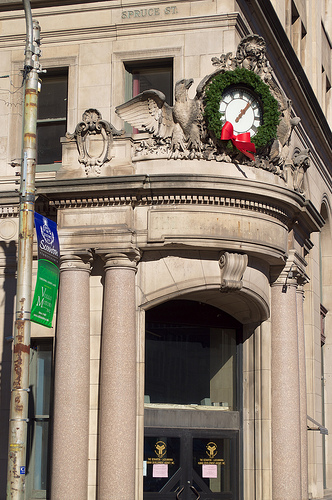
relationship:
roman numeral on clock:
[236, 88, 247, 100] [216, 83, 263, 138]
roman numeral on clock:
[251, 112, 263, 121] [216, 83, 263, 138]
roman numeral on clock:
[227, 90, 236, 99] [216, 83, 263, 138]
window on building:
[192, 436, 235, 493] [0, 0, 330, 498]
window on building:
[91, 28, 192, 152] [56, 11, 309, 280]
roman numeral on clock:
[236, 90, 247, 99] [215, 85, 269, 140]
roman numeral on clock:
[238, 89, 242, 98] [220, 89, 259, 137]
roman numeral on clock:
[229, 90, 234, 99] [220, 89, 259, 137]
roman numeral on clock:
[221, 99, 230, 105] [220, 89, 259, 137]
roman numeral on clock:
[252, 124, 258, 132] [220, 89, 259, 137]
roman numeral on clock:
[217, 111, 225, 115] [220, 89, 259, 137]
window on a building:
[115, 44, 182, 144] [20, 15, 314, 477]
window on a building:
[22, 65, 68, 163] [0, 0, 330, 498]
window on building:
[22, 65, 68, 163] [0, 0, 330, 498]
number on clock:
[236, 92, 245, 101] [194, 74, 274, 131]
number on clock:
[251, 124, 259, 132] [214, 87, 261, 136]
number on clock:
[252, 112, 265, 121] [214, 87, 261, 136]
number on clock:
[228, 93, 235, 100] [214, 87, 261, 136]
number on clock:
[219, 94, 230, 107] [214, 87, 261, 136]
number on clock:
[237, 89, 243, 99] [214, 87, 261, 136]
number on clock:
[252, 112, 265, 121] [214, 81, 267, 145]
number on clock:
[216, 108, 226, 116] [214, 81, 267, 145]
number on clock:
[219, 94, 230, 107] [214, 81, 267, 145]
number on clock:
[228, 93, 235, 100] [214, 81, 267, 145]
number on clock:
[237, 89, 243, 99] [214, 81, 267, 145]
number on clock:
[250, 103, 259, 112] [212, 80, 266, 135]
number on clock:
[250, 103, 259, 112] [196, 58, 280, 158]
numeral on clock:
[251, 121, 260, 129] [199, 64, 276, 157]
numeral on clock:
[219, 113, 226, 120] [213, 91, 272, 140]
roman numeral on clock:
[245, 96, 253, 106] [196, 57, 277, 167]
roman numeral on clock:
[226, 85, 236, 101] [216, 91, 261, 144]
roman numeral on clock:
[236, 89, 245, 99] [216, 83, 263, 138]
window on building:
[127, 282, 281, 427] [0, 0, 330, 498]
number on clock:
[218, 95, 231, 110] [201, 55, 276, 175]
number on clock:
[236, 92, 245, 101] [196, 64, 270, 165]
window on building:
[143, 423, 181, 499] [0, 0, 330, 498]